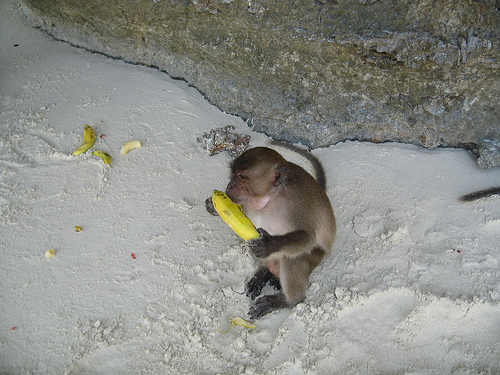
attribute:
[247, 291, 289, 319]
foot — furry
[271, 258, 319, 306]
thigh — furry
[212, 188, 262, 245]
banana — yellow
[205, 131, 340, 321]
monkey — furry, brown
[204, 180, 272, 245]
banana — unpeeled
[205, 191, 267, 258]
banana — yellow, long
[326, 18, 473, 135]
rock — big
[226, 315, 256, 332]
banana skin — yellow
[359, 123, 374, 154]
rock — gray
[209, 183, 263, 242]
banana — yellow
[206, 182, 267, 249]
banana — yellow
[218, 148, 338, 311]
monkey — furry, brown, holding banana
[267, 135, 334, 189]
tail — long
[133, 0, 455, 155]
rock — gray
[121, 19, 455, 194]
wall — hard, rocky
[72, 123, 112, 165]
peel — banana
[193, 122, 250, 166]
object — brown